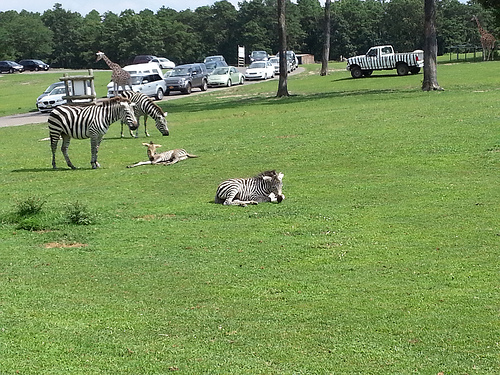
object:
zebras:
[125, 140, 201, 169]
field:
[1, 52, 497, 375]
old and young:
[46, 96, 201, 171]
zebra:
[109, 88, 170, 139]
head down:
[154, 111, 170, 137]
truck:
[345, 44, 425, 79]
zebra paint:
[370, 60, 393, 68]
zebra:
[214, 169, 286, 208]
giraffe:
[94, 50, 134, 94]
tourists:
[215, 70, 224, 75]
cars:
[105, 72, 168, 101]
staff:
[367, 49, 380, 58]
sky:
[0, 0, 244, 19]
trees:
[38, 2, 68, 34]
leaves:
[117, 12, 149, 46]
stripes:
[347, 53, 417, 70]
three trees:
[271, 0, 445, 100]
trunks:
[272, 0, 288, 99]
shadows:
[152, 88, 421, 114]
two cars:
[0, 58, 51, 74]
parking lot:
[0, 67, 111, 78]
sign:
[239, 47, 246, 59]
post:
[237, 44, 239, 67]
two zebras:
[45, 89, 171, 171]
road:
[0, 107, 51, 129]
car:
[163, 62, 209, 95]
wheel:
[180, 82, 192, 94]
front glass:
[208, 67, 231, 76]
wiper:
[223, 69, 229, 74]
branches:
[50, 42, 77, 65]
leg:
[143, 115, 150, 137]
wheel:
[350, 65, 362, 79]